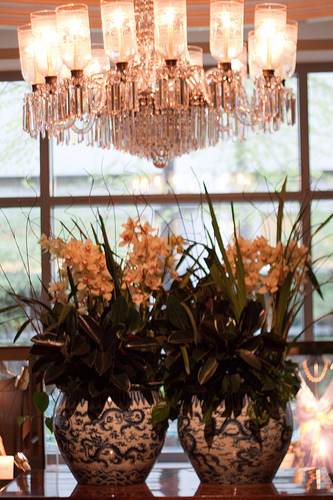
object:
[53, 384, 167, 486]
vase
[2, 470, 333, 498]
table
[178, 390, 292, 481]
vase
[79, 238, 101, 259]
flowers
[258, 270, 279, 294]
flowers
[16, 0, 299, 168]
chandelier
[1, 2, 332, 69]
ceiling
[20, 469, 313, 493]
reflection of light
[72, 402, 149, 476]
design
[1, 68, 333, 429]
window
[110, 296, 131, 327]
leaf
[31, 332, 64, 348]
leaf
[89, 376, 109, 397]
leaf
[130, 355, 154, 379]
leaf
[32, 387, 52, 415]
leaf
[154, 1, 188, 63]
bulb guard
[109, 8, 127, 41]
light bulb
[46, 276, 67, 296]
flower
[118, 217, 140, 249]
flower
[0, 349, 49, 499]
mannequin reflection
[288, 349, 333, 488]
mannequin reflection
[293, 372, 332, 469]
dress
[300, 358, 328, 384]
pearls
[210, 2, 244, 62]
glass flute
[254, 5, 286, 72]
glass flute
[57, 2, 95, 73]
glass flute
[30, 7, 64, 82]
glass flute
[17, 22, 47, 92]
glass flute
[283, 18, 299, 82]
glass flute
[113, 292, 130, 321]
leaf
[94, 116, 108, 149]
pendant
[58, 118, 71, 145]
pendant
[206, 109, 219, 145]
pendant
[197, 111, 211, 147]
pendant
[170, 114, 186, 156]
pendant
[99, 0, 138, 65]
bulb guard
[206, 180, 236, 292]
leaf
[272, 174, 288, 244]
leaf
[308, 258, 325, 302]
leaf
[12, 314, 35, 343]
leaf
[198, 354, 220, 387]
leaf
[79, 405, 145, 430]
dragon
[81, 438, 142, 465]
dragon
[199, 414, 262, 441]
dragon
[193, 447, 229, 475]
dragon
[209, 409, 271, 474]
surface